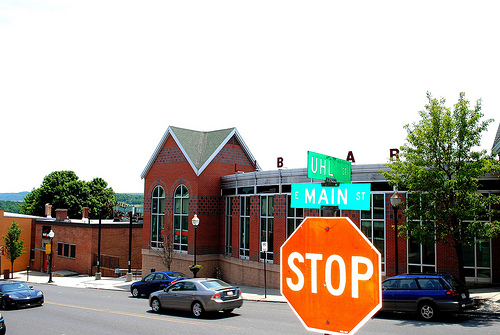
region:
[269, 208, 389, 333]
red stop sign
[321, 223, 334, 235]
metal bolt on stop sign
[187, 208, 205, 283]
tall street lamp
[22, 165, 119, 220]
tall green trees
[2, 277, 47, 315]
black corvette driving down street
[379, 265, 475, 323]
blue station wagon parked next to sidewalk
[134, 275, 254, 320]
beige four door car travelling on street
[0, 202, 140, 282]
red brick building on sidewalk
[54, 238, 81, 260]
three black windows on side of brick building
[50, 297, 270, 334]
yellow line drawn on middle of street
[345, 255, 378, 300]
white letter on a sign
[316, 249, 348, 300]
white letter on a sign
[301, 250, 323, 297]
white letter on a sign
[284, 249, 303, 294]
white letter on a sign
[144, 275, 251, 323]
car on the street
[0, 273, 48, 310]
car on the street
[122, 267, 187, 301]
car on the street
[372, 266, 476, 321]
car on the street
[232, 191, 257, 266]
window of a building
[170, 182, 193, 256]
window of a building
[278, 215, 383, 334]
The stop sign is bright red.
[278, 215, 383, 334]
The stop sign has a white boarder.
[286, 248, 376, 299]
The stop sign letters are white.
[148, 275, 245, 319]
The car is gray.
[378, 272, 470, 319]
The van is blue.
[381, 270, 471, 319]
The van is partially hidden behind the stop sign.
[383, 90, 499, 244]
The tree's leaves are green.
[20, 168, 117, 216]
The tree's leaves are green.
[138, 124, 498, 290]
The building is made of red brick.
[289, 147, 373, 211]
The street signs are a very bright green.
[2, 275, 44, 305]
a black car going north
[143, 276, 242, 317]
a grey 4 door moving south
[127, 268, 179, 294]
a blue sedan parked on right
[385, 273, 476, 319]
a station wagon in curve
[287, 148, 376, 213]
double green sign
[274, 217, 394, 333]
a red stop sign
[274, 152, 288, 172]
b on top of building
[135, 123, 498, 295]
a brick building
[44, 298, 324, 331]
yellow line in street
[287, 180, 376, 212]
main street on sign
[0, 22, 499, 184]
clear daylight in sky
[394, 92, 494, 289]
green leaves on tree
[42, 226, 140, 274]
corner of brick building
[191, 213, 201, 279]
light on black pole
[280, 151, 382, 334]
two street sign over stop sign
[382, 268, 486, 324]
blue car parked in shade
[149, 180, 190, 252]
two arched shaped windows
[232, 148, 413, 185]
letters on curved roof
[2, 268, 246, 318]
three cars on street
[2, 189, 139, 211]
trees on distant horizon